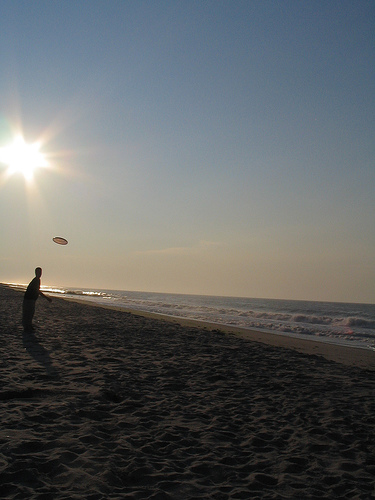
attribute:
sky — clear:
[2, 1, 374, 303]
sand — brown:
[161, 377, 255, 437]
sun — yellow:
[0, 129, 55, 188]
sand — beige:
[11, 368, 356, 494]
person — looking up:
[21, 264, 52, 336]